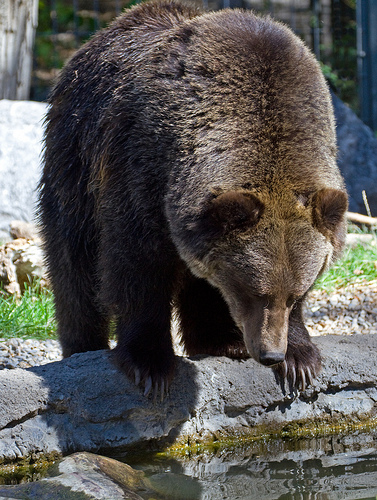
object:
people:
[27, 0, 84, 100]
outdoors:
[327, 1, 377, 105]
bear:
[23, 0, 357, 402]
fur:
[83, 39, 298, 149]